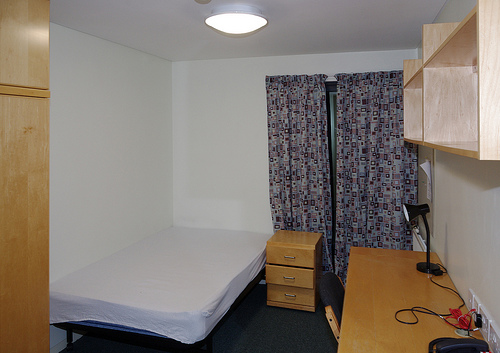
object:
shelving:
[402, 0, 497, 161]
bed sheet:
[47, 227, 274, 344]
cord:
[395, 263, 477, 340]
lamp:
[403, 203, 441, 274]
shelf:
[400, 0, 499, 160]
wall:
[440, 163, 500, 325]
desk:
[337, 245, 492, 353]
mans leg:
[385, 16, 483, 157]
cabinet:
[399, 0, 480, 152]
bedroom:
[0, 0, 500, 353]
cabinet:
[0, 1, 49, 353]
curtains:
[264, 70, 418, 288]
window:
[268, 80, 418, 268]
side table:
[265, 229, 324, 312]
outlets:
[467, 290, 500, 353]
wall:
[439, 154, 500, 333]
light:
[203, 1, 268, 39]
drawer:
[265, 231, 325, 314]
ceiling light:
[203, 5, 269, 34]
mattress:
[48, 230, 274, 346]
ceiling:
[48, 0, 481, 62]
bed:
[48, 226, 274, 353]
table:
[337, 247, 492, 353]